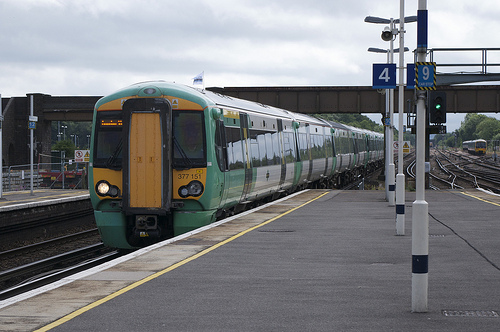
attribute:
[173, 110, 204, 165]
window — tinted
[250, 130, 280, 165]
window — large, long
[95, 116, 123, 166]
window — tinted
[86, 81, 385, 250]
train — green, yellow, large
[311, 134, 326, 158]
window — large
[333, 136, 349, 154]
window — tinted, long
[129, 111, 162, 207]
door — yellow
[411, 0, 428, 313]
post — black, white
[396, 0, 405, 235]
post — black, white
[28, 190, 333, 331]
line — yellow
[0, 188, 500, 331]
pavement —  gray, grey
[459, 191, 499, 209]
line — yellow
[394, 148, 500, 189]
train tracks —  train's,  criss cross, empty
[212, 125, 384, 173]
side windows — shiny, black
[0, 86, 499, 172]
bridge —  black,    iron,     in  air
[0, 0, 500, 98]
skies — cloudy